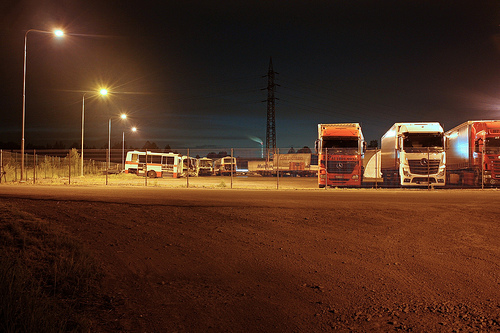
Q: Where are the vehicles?
A: Behind the fence.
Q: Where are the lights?
A: On the light poles.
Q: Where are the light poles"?
A: In the enclosure.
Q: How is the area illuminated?
A: Lights on poles.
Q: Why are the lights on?
A: To see in darkness.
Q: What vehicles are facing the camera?
A: Tractor trailers.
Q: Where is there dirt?
A: Ground.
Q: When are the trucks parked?
A: During the night.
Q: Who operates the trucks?
A: Drivers.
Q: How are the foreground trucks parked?
A: In a row.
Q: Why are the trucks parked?
A: Not in use.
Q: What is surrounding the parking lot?
A: Fence.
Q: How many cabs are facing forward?
A: Three.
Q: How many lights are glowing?
A: Four.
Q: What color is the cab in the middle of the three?
A: White.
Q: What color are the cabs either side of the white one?
A: Orange.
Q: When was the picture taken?
A: Night time.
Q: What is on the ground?
A: Dirt.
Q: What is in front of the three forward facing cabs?
A: A fence.